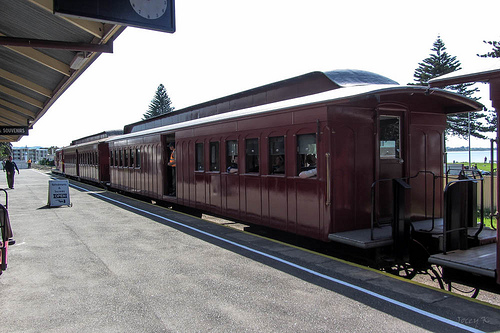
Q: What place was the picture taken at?
A: It was taken at the station.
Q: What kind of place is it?
A: It is a station.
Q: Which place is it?
A: It is a station.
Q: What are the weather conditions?
A: It is cloudy.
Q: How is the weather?
A: It is cloudy.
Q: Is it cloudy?
A: Yes, it is cloudy.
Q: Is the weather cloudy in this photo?
A: Yes, it is cloudy.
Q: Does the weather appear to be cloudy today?
A: Yes, it is cloudy.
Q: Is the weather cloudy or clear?
A: It is cloudy.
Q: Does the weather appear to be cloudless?
A: No, it is cloudy.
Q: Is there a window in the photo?
A: Yes, there is a window.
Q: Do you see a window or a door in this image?
A: Yes, there is a window.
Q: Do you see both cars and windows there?
A: Yes, there are both a window and a car.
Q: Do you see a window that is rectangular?
A: Yes, there is a rectangular window.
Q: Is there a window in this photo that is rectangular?
A: Yes, there is a window that is rectangular.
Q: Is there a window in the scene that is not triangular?
A: Yes, there is a rectangular window.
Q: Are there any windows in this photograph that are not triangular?
A: Yes, there is a rectangular window.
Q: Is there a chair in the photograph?
A: No, there are no chairs.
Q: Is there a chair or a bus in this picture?
A: No, there are no chairs or buses.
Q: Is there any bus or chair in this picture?
A: No, there are no chairs or buses.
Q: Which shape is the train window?
A: The window is rectangular.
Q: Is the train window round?
A: No, the window is rectangular.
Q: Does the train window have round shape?
A: No, the window is rectangular.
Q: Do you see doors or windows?
A: Yes, there is a window.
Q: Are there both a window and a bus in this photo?
A: No, there is a window but no buses.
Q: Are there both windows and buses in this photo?
A: No, there is a window but no buses.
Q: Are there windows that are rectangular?
A: Yes, there is a window that is rectangular.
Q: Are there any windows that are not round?
A: Yes, there is a rectangular window.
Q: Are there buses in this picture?
A: No, there are no buses.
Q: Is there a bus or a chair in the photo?
A: No, there are no buses or chairs.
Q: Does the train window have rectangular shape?
A: Yes, the window is rectangular.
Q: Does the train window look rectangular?
A: Yes, the window is rectangular.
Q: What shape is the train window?
A: The window is rectangular.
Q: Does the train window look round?
A: No, the window is rectangular.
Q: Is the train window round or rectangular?
A: The window is rectangular.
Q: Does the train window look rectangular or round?
A: The window is rectangular.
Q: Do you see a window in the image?
A: Yes, there is a window.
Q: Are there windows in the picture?
A: Yes, there is a window.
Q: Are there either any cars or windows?
A: Yes, there is a window.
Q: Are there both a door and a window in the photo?
A: Yes, there are both a window and a door.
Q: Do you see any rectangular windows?
A: Yes, there is a rectangular window.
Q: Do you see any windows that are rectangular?
A: Yes, there is a window that is rectangular.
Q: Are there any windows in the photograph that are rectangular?
A: Yes, there is a window that is rectangular.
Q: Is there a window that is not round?
A: Yes, there is a rectangular window.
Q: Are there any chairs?
A: No, there are no chairs.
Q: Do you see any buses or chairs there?
A: No, there are no chairs or buses.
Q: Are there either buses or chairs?
A: No, there are no chairs or buses.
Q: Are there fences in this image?
A: No, there are no fences.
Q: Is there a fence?
A: No, there are no fences.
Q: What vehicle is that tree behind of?
A: The tree is behind the train.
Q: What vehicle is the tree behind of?
A: The tree is behind the train.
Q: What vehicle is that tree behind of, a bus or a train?
A: The tree is behind a train.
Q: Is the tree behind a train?
A: Yes, the tree is behind a train.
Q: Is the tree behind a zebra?
A: No, the tree is behind a train.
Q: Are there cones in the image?
A: No, there are no cones.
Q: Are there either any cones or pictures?
A: No, there are no cones or pictures.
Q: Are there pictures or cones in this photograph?
A: No, there are no cones or pictures.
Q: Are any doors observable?
A: Yes, there is a door.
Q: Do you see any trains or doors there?
A: Yes, there is a door.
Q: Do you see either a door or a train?
A: Yes, there is a door.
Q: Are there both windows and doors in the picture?
A: Yes, there are both a door and a window.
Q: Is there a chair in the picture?
A: No, there are no chairs.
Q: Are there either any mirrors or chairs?
A: No, there are no chairs or mirrors.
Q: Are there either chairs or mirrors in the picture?
A: No, there are no chairs or mirrors.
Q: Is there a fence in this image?
A: No, there are no fences.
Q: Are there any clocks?
A: Yes, there is a clock.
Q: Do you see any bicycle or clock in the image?
A: Yes, there is a clock.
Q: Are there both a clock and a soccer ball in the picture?
A: No, there is a clock but no soccer balls.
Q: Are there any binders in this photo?
A: No, there are no binders.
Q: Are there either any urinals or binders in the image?
A: No, there are no binders or urinals.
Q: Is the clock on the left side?
A: Yes, the clock is on the left of the image.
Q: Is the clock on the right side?
A: No, the clock is on the left of the image.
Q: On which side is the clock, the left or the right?
A: The clock is on the left of the image.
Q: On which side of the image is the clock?
A: The clock is on the left of the image.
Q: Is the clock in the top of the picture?
A: Yes, the clock is in the top of the image.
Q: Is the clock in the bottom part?
A: No, the clock is in the top of the image.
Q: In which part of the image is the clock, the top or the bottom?
A: The clock is in the top of the image.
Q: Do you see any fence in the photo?
A: No, there are no fences.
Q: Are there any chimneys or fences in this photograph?
A: No, there are no fences or chimneys.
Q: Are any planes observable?
A: No, there are no planes.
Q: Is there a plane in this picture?
A: No, there are no airplanes.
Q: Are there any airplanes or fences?
A: No, there are no airplanes or fences.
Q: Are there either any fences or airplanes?
A: No, there are no airplanes or fences.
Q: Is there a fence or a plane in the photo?
A: No, there are no airplanes or fences.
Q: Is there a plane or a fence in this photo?
A: No, there are no airplanes or fences.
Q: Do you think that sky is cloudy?
A: Yes, the sky is cloudy.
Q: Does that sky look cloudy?
A: Yes, the sky is cloudy.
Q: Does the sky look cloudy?
A: Yes, the sky is cloudy.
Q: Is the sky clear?
A: No, the sky is cloudy.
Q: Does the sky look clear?
A: No, the sky is cloudy.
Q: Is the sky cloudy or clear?
A: The sky is cloudy.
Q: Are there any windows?
A: Yes, there is a window.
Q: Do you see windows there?
A: Yes, there is a window.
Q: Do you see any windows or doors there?
A: Yes, there is a window.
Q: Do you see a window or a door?
A: Yes, there is a window.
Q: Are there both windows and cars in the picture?
A: Yes, there are both a window and a car.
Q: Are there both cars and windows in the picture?
A: Yes, there are both a window and a car.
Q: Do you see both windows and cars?
A: Yes, there are both a window and a car.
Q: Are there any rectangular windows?
A: Yes, there is a rectangular window.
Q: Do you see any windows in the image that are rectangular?
A: Yes, there is a window that is rectangular.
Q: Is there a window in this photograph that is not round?
A: Yes, there is a rectangular window.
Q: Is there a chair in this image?
A: No, there are no chairs.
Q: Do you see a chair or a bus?
A: No, there are no chairs or buses.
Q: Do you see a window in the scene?
A: Yes, there is a window.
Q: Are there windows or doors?
A: Yes, there is a window.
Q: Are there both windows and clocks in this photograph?
A: Yes, there are both a window and a clock.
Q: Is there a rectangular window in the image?
A: Yes, there is a rectangular window.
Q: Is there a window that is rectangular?
A: Yes, there is a window that is rectangular.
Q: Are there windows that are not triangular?
A: Yes, there is a rectangular window.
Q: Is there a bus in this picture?
A: No, there are no buses.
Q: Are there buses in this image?
A: No, there are no buses.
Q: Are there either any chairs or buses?
A: No, there are no buses or chairs.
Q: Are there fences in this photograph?
A: No, there are no fences.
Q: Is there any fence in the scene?
A: No, there are no fences.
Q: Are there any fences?
A: No, there are no fences.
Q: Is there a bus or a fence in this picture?
A: No, there are no fences or buses.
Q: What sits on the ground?
A: The sign sits on the ground.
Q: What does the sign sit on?
A: The sign sits on the ground.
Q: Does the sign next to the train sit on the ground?
A: Yes, the sign sits on the ground.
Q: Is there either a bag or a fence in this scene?
A: No, there are no fences or bags.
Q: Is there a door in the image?
A: Yes, there is a door.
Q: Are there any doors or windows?
A: Yes, there is a door.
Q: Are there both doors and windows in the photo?
A: Yes, there are both a door and windows.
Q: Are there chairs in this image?
A: No, there are no chairs.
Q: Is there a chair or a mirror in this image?
A: No, there are no chairs or mirrors.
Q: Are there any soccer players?
A: No, there are no soccer players.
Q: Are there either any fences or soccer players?
A: No, there are no soccer players or fences.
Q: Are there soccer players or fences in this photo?
A: No, there are no soccer players or fences.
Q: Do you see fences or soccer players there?
A: No, there are no soccer players or fences.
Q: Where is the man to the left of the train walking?
A: The man is walking on the sidewalk.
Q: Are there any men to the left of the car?
A: Yes, there is a man to the left of the car.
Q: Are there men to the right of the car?
A: No, the man is to the left of the car.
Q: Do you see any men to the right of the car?
A: No, the man is to the left of the car.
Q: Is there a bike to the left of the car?
A: No, there is a man to the left of the car.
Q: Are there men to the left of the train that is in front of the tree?
A: Yes, there is a man to the left of the train.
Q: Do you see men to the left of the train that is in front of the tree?
A: Yes, there is a man to the left of the train.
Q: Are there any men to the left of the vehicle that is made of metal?
A: Yes, there is a man to the left of the train.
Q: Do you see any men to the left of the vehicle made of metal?
A: Yes, there is a man to the left of the train.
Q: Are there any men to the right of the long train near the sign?
A: No, the man is to the left of the train.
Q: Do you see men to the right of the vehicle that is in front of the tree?
A: No, the man is to the left of the train.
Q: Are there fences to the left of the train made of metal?
A: No, there is a man to the left of the train.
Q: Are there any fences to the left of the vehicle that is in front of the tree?
A: No, there is a man to the left of the train.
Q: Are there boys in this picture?
A: No, there are no boys.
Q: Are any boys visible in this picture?
A: No, there are no boys.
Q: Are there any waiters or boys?
A: No, there are no boys or waiters.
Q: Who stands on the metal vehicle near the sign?
A: The man stands on the train.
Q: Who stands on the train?
A: The man stands on the train.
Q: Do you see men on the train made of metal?
A: Yes, there is a man on the train.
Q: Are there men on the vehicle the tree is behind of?
A: Yes, there is a man on the train.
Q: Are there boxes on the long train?
A: No, there is a man on the train.